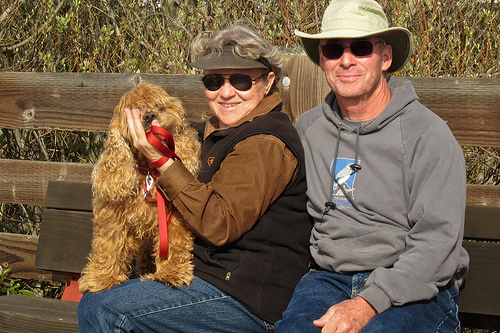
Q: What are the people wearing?
A: Hats.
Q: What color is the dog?
A: Brown.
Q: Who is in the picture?
A: A man, woman, and dog.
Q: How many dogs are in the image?
A: One.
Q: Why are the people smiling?
A: They are posing for the photo.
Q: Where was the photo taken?
A: Outdoors on a bench.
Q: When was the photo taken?
A: A sunny day.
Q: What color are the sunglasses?
A: Black.